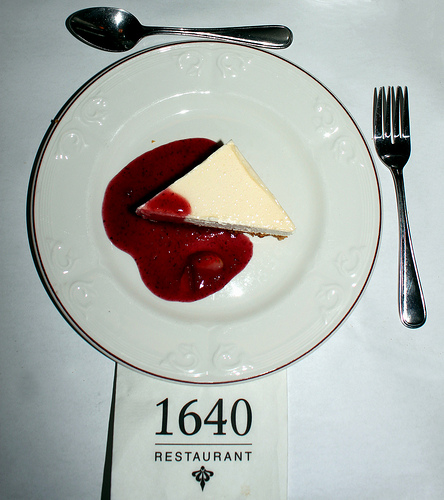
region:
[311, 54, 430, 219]
a silver fork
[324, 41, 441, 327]
a silver fork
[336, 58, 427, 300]
a silver fork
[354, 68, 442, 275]
a silver fork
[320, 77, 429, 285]
a silver fork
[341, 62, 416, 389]
a silver fork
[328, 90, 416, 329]
a silver fork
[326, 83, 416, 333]
a silver fork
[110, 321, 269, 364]
The plate is white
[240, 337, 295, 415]
The plate is white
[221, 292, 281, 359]
The plate is white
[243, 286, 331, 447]
The plate is white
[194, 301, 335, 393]
The plate is white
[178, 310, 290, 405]
The plate is white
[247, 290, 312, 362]
The plate is white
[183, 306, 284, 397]
The plate is white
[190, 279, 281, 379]
The plate is white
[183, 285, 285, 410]
The plate is white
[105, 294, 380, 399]
The plate is white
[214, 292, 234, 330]
The plate is white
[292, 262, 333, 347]
The plate is white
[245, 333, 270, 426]
The plate is white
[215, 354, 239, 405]
The plate is white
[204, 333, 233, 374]
The plate is white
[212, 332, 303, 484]
The plate is white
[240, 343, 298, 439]
The plate is white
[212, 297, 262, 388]
The plate is white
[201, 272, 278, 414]
The plate is white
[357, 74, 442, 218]
A stainless steel fork.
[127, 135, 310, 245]
Strawberry cheesecake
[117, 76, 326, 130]
A white plate which strawberry cheesecake on it.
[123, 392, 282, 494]
A piece of paper that says "1640 Restaurant".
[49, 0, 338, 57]
A stainless steel spoon.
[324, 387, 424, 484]
A white tablecloth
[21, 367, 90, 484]
A white tablecloth.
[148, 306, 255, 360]
A part of a plate holding strawberry cheesecake.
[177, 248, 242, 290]
A piece of strawberry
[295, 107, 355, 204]
A part of a plate with strawberry cheesecake on it.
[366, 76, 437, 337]
four prong metal fork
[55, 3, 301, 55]
shinny metal spoon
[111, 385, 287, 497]
advertisement for 1640 Restaurant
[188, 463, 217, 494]
decorative black emblem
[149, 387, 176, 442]
number one in bold black font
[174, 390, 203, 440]
number six in bold black font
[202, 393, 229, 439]
number four in bold black font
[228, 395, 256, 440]
number zero in bold black font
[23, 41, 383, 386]
dessert on a large white plate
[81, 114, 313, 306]
cheesecake with strawberry sauce